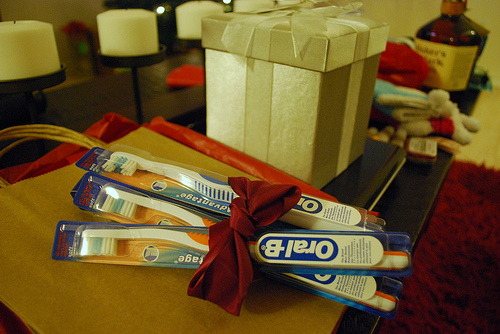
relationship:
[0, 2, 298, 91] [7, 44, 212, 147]
candles are on candle holders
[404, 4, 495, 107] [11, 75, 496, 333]
liquor bottle on table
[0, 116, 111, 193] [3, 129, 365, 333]
handles of gift bags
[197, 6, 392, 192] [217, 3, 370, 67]
gift box has bow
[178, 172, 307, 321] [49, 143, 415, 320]
red bow on toothbrushes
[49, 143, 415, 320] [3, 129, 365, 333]
toothbrushes are on gift bags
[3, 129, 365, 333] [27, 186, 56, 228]
gift bags are made of paper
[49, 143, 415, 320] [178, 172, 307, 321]
toothbrushes are held with red bow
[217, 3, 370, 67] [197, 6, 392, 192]
bow on gift box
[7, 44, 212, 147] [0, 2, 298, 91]
candle holders with candles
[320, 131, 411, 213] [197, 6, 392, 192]
laptop under gift box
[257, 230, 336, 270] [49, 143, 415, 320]
brand on toothbrushes